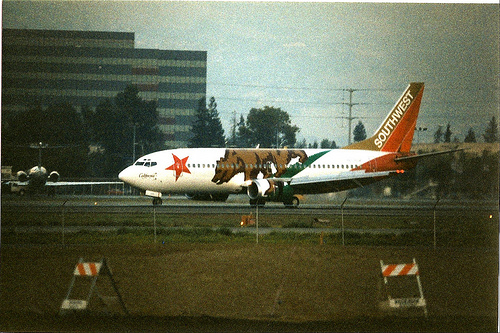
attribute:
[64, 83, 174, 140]
tree — big 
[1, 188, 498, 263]
fence — grey , metal 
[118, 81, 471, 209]
airplane — white, Southwest-owned, brown 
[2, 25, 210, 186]
building — pictured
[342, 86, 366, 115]
cable — power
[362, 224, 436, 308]
barrier — orange, white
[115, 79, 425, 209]
plane — pictured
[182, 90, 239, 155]
tree — pictured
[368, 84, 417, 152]
letters — Southwest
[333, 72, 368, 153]
electrical pole — brown , wood 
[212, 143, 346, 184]
bear — California flag, brown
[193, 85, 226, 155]
tree — big 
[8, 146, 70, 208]
plane — grey 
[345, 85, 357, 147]
power pole — pictured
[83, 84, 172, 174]
tree — big 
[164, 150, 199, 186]
star — five-point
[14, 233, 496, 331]
green grass — pictured